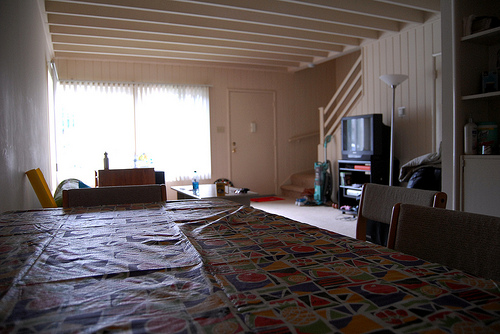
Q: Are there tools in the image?
A: No, there are no tools.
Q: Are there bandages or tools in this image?
A: No, there are no tools or bandages.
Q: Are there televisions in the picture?
A: Yes, there is a television.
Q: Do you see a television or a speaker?
A: Yes, there is a television.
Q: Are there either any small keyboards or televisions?
A: Yes, there is a small television.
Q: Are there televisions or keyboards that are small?
A: Yes, the television is small.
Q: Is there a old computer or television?
A: Yes, there is an old television.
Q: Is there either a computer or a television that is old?
A: Yes, the television is old.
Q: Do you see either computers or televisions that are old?
A: Yes, the television is old.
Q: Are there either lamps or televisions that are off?
A: Yes, the television is off.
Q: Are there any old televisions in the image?
A: Yes, there is an old television.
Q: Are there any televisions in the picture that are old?
A: Yes, there is a television that is old.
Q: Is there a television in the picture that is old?
A: Yes, there is a television that is old.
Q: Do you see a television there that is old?
A: Yes, there is a television that is old.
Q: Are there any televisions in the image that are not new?
A: Yes, there is a old television.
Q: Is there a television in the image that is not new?
A: Yes, there is a old television.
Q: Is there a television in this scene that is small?
A: Yes, there is a small television.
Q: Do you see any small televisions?
A: Yes, there is a small television.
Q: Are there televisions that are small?
A: Yes, there is a television that is small.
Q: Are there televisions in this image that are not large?
A: Yes, there is a small television.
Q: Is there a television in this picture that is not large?
A: Yes, there is a small television.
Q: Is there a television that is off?
A: Yes, there is a television that is off.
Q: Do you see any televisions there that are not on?
A: Yes, there is a television that is off .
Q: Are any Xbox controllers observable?
A: No, there are no Xbox controllers.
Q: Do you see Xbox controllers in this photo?
A: No, there are no Xbox controllers.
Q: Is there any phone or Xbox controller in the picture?
A: No, there are no Xbox controllers or phones.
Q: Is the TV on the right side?
A: Yes, the TV is on the right of the image.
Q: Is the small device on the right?
A: Yes, the TV is on the right of the image.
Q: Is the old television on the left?
A: No, the television is on the right of the image.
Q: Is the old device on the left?
A: No, the television is on the right of the image.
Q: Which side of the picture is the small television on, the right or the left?
A: The television is on the right of the image.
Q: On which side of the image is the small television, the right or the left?
A: The television is on the right of the image.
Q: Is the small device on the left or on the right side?
A: The television is on the right of the image.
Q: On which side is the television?
A: The television is on the right of the image.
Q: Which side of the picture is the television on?
A: The television is on the right of the image.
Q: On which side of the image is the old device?
A: The television is on the right of the image.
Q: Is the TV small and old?
A: Yes, the TV is small and old.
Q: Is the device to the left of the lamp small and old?
A: Yes, the TV is small and old.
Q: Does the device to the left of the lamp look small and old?
A: Yes, the TV is small and old.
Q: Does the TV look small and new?
A: No, the TV is small but old.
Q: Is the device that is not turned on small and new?
A: No, the TV is small but old.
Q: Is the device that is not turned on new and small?
A: No, the TV is small but old.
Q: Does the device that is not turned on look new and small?
A: No, the TV is small but old.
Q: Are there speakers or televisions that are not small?
A: No, there is a television but it is small.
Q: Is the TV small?
A: Yes, the TV is small.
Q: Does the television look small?
A: Yes, the television is small.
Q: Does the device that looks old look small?
A: Yes, the television is small.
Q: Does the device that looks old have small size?
A: Yes, the television is small.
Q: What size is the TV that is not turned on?
A: The TV is small.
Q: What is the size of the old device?
A: The TV is small.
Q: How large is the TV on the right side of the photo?
A: The TV is small.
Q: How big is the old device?
A: The TV is small.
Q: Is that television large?
A: No, the television is small.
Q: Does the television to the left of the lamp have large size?
A: No, the TV is small.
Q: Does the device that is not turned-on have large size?
A: No, the TV is small.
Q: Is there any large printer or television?
A: No, there is a television but it is small.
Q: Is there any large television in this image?
A: No, there is a television but it is small.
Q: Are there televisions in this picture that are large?
A: No, there is a television but it is small.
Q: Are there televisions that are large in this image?
A: No, there is a television but it is small.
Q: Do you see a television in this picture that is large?
A: No, there is a television but it is small.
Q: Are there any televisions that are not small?
A: No, there is a television but it is small.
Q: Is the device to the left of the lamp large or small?
A: The TV is small.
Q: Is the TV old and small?
A: Yes, the TV is old and small.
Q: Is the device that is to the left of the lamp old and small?
A: Yes, the TV is old and small.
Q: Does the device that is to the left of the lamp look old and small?
A: Yes, the TV is old and small.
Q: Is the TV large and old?
A: No, the TV is old but small.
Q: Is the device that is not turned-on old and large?
A: No, the TV is old but small.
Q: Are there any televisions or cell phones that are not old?
A: No, there is a television but it is old.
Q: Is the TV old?
A: Yes, the TV is old.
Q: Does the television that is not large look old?
A: Yes, the TV is old.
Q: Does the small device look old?
A: Yes, the TV is old.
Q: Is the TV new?
A: No, the TV is old.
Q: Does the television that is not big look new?
A: No, the TV is old.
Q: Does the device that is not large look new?
A: No, the TV is old.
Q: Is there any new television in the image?
A: No, there is a television but it is old.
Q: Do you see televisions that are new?
A: No, there is a television but it is old.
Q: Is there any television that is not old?
A: No, there is a television but it is old.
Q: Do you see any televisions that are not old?
A: No, there is a television but it is old.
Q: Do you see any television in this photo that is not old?
A: No, there is a television but it is old.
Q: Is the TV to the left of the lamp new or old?
A: The TV is old.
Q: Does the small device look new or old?
A: The TV is old.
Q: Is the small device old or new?
A: The TV is old.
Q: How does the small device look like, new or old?
A: The TV is old.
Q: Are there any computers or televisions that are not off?
A: No, there is a television but it is off.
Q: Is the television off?
A: Yes, the television is off.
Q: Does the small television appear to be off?
A: Yes, the television is off.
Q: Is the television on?
A: No, the television is off.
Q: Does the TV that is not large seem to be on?
A: No, the television is off.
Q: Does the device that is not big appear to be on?
A: No, the television is off.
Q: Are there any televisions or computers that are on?
A: No, there is a television but it is off.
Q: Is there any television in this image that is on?
A: No, there is a television but it is off.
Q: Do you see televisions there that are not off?
A: No, there is a television but it is off.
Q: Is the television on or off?
A: The television is off.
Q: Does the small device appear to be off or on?
A: The television is off.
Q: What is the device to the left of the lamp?
A: The device is a television.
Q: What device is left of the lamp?
A: The device is a television.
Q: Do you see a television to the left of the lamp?
A: Yes, there is a television to the left of the lamp.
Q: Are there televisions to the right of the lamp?
A: No, the television is to the left of the lamp.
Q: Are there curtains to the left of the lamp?
A: No, there is a television to the left of the lamp.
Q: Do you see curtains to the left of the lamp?
A: No, there is a television to the left of the lamp.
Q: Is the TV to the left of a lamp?
A: Yes, the TV is to the left of a lamp.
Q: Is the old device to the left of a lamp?
A: Yes, the TV is to the left of a lamp.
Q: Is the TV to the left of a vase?
A: No, the TV is to the left of a lamp.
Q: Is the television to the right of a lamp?
A: No, the television is to the left of a lamp.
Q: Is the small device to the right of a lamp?
A: No, the television is to the left of a lamp.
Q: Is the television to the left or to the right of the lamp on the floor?
A: The television is to the left of the lamp.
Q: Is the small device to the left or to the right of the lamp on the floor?
A: The television is to the left of the lamp.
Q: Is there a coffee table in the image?
A: Yes, there is a coffee table.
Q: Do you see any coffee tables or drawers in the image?
A: Yes, there is a coffee table.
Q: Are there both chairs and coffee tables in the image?
A: Yes, there are both a coffee table and a chair.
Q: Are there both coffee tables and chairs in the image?
A: Yes, there are both a coffee table and a chair.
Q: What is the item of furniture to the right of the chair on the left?
A: The piece of furniture is a coffee table.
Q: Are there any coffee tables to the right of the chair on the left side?
A: Yes, there is a coffee table to the right of the chair.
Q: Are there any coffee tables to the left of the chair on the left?
A: No, the coffee table is to the right of the chair.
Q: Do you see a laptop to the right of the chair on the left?
A: No, there is a coffee table to the right of the chair.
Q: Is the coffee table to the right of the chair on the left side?
A: Yes, the coffee table is to the right of the chair.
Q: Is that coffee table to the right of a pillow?
A: No, the coffee table is to the right of the chair.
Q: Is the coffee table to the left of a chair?
A: No, the coffee table is to the right of a chair.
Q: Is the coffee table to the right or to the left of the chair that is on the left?
A: The coffee table is to the right of the chair.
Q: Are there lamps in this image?
A: Yes, there is a lamp.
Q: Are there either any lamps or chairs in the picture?
A: Yes, there is a lamp.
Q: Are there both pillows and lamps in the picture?
A: No, there is a lamp but no pillows.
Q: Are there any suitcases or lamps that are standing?
A: Yes, the lamp is standing.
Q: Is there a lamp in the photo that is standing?
A: Yes, there is a lamp that is standing.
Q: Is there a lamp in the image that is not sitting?
A: Yes, there is a lamp that is standing.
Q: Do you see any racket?
A: No, there are no rackets.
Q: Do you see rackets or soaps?
A: No, there are no rackets or soaps.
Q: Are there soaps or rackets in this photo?
A: No, there are no rackets or soaps.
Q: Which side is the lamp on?
A: The lamp is on the right of the image.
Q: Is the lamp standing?
A: Yes, the lamp is standing.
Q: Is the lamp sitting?
A: No, the lamp is standing.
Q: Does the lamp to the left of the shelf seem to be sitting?
A: No, the lamp is standing.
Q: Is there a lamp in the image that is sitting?
A: No, there is a lamp but it is standing.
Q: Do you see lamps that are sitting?
A: No, there is a lamp but it is standing.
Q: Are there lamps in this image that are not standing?
A: No, there is a lamp but it is standing.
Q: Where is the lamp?
A: The lamp is on the floor.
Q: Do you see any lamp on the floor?
A: Yes, there is a lamp on the floor.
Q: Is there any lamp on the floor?
A: Yes, there is a lamp on the floor.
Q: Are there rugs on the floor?
A: No, there is a lamp on the floor.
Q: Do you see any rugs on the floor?
A: No, there is a lamp on the floor.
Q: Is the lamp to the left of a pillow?
A: No, the lamp is to the left of the shelf.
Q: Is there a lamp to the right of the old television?
A: Yes, there is a lamp to the right of the TV.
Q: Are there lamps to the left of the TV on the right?
A: No, the lamp is to the right of the TV.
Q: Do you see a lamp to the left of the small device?
A: No, the lamp is to the right of the TV.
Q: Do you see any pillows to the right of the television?
A: No, there is a lamp to the right of the television.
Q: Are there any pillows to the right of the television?
A: No, there is a lamp to the right of the television.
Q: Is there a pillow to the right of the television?
A: No, there is a lamp to the right of the television.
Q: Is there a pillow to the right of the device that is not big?
A: No, there is a lamp to the right of the television.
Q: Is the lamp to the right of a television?
A: Yes, the lamp is to the right of a television.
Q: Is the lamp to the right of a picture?
A: No, the lamp is to the right of a television.